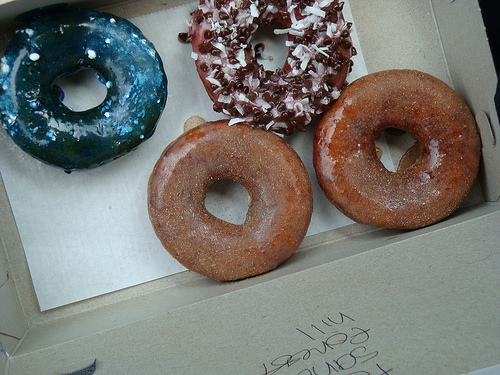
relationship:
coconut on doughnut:
[273, 27, 295, 37] [181, 0, 357, 140]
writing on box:
[263, 313, 391, 374] [0, 0, 499, 373]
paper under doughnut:
[0, 0, 398, 311] [181, 0, 357, 140]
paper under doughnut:
[0, 0, 398, 311] [0, 11, 167, 174]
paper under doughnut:
[0, 0, 398, 311] [149, 118, 314, 281]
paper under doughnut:
[0, 0, 398, 311] [316, 65, 479, 230]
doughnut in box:
[181, 0, 357, 140] [0, 0, 499, 373]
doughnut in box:
[0, 11, 167, 174] [0, 0, 499, 373]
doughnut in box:
[149, 118, 314, 281] [0, 0, 499, 373]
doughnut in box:
[316, 65, 479, 230] [0, 0, 499, 373]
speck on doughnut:
[314, 45, 328, 56] [181, 0, 357, 140]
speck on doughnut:
[294, 101, 305, 113] [181, 0, 357, 140]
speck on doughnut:
[207, 74, 220, 90] [181, 0, 357, 140]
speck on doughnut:
[214, 37, 228, 54] [181, 0, 357, 140]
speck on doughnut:
[250, 3, 262, 21] [181, 0, 357, 140]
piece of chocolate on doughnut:
[272, 83, 283, 95] [181, 0, 357, 140]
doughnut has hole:
[181, 0, 357, 140] [251, 19, 292, 74]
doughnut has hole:
[0, 11, 167, 174] [50, 56, 107, 111]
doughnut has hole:
[149, 118, 314, 281] [199, 175, 252, 226]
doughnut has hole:
[316, 65, 479, 230] [371, 119, 422, 173]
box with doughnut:
[0, 0, 499, 373] [181, 0, 357, 140]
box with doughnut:
[0, 0, 499, 373] [0, 11, 167, 174]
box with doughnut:
[0, 0, 499, 373] [149, 118, 314, 281]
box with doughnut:
[0, 0, 499, 373] [316, 65, 479, 230]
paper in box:
[0, 0, 398, 311] [0, 0, 499, 373]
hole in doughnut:
[371, 119, 422, 173] [316, 65, 479, 230]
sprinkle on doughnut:
[28, 50, 41, 64] [0, 11, 167, 174]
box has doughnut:
[0, 0, 499, 373] [181, 0, 357, 140]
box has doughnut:
[0, 0, 499, 373] [0, 11, 167, 174]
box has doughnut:
[0, 0, 499, 373] [149, 118, 314, 281]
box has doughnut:
[0, 0, 499, 373] [316, 65, 479, 230]